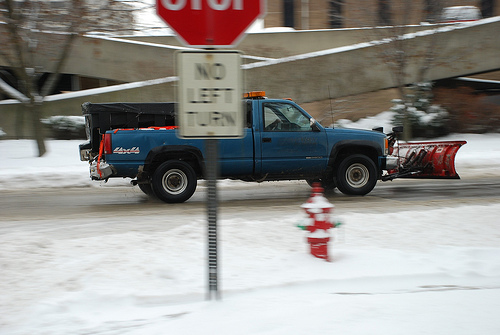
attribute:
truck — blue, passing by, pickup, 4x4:
[78, 89, 474, 204]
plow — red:
[385, 125, 468, 182]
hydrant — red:
[294, 180, 346, 265]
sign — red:
[153, 1, 267, 49]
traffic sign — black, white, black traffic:
[176, 49, 246, 143]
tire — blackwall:
[336, 154, 379, 198]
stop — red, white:
[159, 2, 250, 14]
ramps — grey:
[1, 16, 500, 141]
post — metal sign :
[206, 137, 221, 294]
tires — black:
[152, 153, 389, 203]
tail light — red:
[102, 133, 114, 157]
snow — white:
[1, 132, 499, 335]